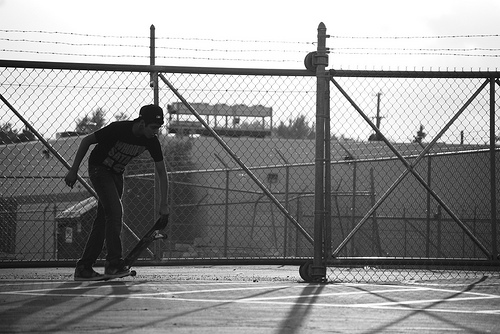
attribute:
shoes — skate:
[71, 257, 131, 284]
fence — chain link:
[202, 83, 297, 239]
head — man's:
[132, 102, 165, 141]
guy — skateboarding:
[54, 97, 231, 261]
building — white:
[1, 132, 498, 260]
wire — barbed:
[2, 26, 497, 68]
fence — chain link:
[2, 27, 498, 287]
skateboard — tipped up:
[113, 217, 179, 268]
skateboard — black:
[122, 207, 174, 275]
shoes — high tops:
[72, 246, 132, 273]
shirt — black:
[91, 120, 164, 171]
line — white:
[365, 289, 497, 310]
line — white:
[239, 285, 422, 302]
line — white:
[134, 281, 306, 297]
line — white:
[20, 279, 130, 293]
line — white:
[3, 289, 499, 318]